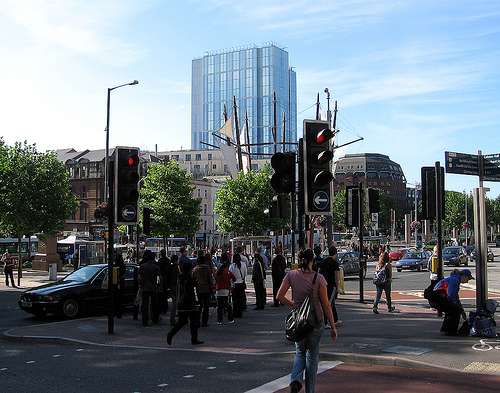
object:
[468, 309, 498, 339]
item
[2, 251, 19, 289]
person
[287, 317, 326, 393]
jeans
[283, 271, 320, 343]
bag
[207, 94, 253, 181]
arrow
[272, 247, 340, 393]
girl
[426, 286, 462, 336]
pants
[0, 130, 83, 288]
tree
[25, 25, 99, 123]
clouds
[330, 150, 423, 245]
building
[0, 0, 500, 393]
city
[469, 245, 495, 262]
car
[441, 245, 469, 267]
car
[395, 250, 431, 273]
car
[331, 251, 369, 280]
car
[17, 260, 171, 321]
car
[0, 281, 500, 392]
pavement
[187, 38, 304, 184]
building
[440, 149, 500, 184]
street sign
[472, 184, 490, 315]
pole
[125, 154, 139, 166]
lights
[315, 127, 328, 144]
light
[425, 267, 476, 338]
kneeling down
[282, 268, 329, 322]
shirt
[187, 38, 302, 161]
scraper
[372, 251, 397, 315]
person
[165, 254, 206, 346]
person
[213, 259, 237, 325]
person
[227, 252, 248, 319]
person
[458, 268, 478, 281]
cap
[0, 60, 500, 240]
background